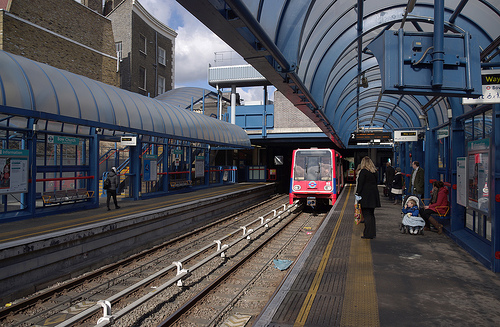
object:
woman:
[354, 155, 383, 238]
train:
[287, 146, 342, 211]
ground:
[261, 171, 499, 325]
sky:
[129, 0, 283, 105]